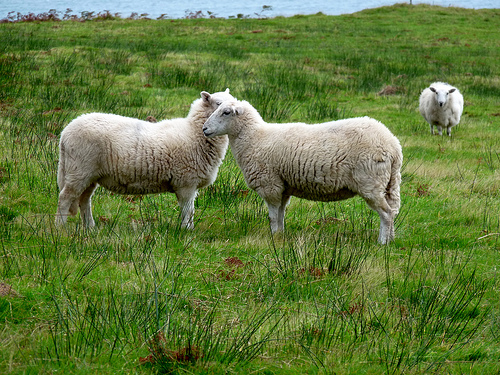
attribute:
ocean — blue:
[104, 1, 161, 20]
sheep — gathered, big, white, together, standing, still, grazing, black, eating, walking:
[52, 72, 412, 244]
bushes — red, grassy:
[117, 295, 206, 362]